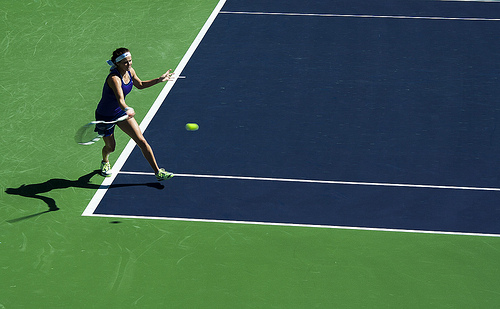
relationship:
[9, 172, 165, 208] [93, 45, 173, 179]
shadow of player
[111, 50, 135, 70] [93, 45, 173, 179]
head of player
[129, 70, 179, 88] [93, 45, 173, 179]
arm of player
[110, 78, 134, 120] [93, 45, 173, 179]
arm of player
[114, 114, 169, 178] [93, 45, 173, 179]
leg of player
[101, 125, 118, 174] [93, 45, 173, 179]
leg of player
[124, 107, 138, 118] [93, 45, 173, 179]
hand of player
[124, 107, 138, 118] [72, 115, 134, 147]
hand holding racket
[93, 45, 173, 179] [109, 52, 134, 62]
player wearing band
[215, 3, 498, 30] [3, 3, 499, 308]
line of court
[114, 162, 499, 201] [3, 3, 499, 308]
line of court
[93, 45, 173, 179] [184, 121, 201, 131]
player hitting ball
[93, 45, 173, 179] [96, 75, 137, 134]
player wearing outfit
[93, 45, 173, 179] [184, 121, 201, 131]
player trying to hit ball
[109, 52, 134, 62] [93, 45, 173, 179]
band on head of player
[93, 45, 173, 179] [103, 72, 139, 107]
player wearing tank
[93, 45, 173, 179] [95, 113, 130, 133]
player wearing shorts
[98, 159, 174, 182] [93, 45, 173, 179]
shoes of player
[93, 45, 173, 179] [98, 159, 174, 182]
player wearing shoes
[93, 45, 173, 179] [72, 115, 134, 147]
player holding racket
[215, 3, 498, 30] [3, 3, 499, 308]
line on top of court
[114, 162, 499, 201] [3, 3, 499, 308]
line on top of court